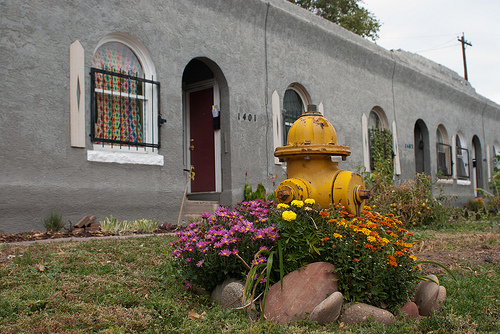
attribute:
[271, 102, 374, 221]
hydrant — yellow, weathered, mettalic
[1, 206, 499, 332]
yard — spotted, brown, green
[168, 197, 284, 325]
flowers — purple, clustered, pink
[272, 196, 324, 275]
marigolds — yellow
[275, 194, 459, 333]
flowers — yellow, orange, mixed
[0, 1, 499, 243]
stone — grey, gray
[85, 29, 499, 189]
windows — arched, oval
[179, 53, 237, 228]
archway — arched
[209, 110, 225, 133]
mailbox — black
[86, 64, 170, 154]
bars — black, mettalic, metal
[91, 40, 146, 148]
curtains — colorful, multicolored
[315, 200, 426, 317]
flowers — orange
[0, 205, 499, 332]
ground vegitation — green, brown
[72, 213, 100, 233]
bricks — piled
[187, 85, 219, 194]
door — closed, maroon, red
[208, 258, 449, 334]
rocks — decorative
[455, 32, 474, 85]
pole — wood, electrical, standing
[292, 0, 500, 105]
sky — cloudy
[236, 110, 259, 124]
numbers — black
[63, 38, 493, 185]
shutter — white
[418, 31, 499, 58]
wires — electric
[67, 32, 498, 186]
frames — white